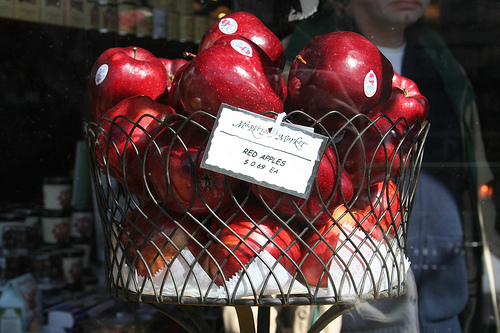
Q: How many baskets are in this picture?
A: One.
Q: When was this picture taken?
A: During the day.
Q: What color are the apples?
A: Red.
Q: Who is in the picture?
A: A man.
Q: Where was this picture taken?
A: Inside a store.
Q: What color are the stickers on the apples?
A: White.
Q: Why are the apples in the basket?
A: To sell.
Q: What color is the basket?
A: Black.